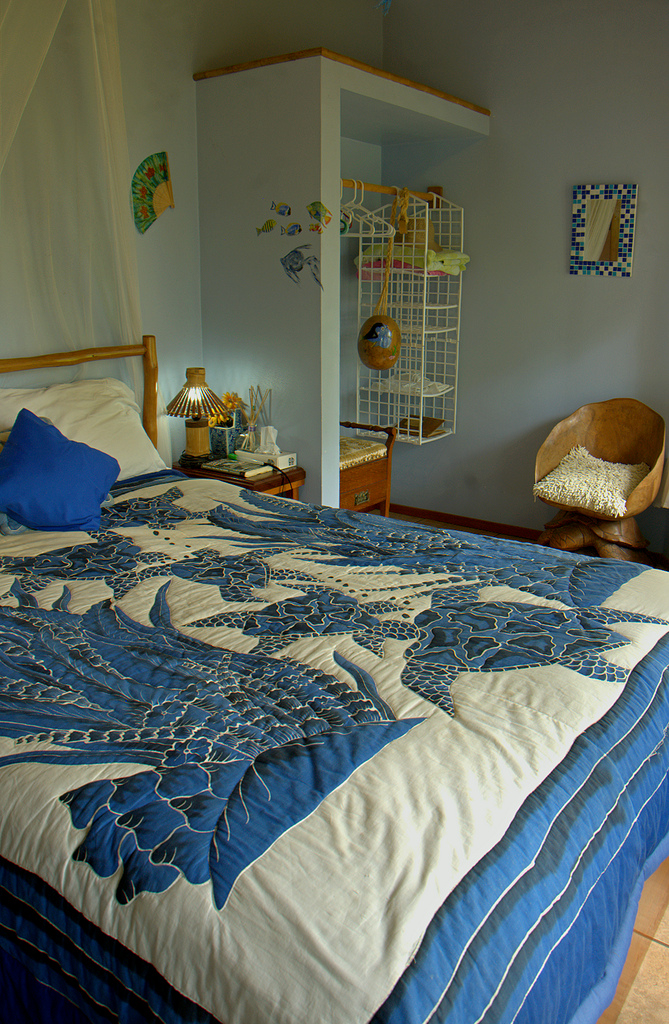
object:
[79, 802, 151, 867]
fabric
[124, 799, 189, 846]
fabric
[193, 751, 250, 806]
fabric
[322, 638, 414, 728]
fabric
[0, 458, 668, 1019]
blanket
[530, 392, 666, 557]
chair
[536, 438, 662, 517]
pillow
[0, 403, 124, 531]
pillow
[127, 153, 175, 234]
fan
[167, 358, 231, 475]
lamp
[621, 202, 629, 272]
mosaic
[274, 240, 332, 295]
sticker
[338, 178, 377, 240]
hanger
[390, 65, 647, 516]
wall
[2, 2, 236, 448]
wall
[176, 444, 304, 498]
table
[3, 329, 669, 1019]
bed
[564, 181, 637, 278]
mirror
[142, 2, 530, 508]
wall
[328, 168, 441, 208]
rod